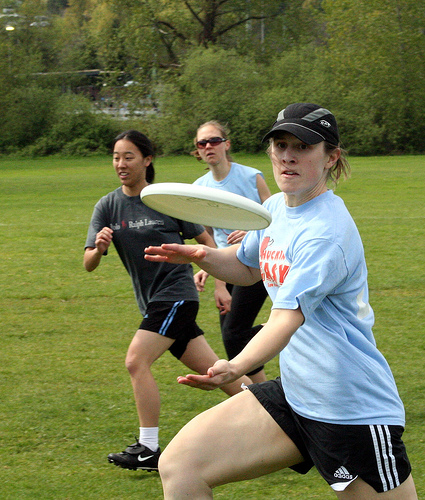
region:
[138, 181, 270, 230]
flying white frizbee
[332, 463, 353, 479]
logo on black pants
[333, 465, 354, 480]
white adidas symbol on shorts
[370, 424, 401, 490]
decorative stripes on pants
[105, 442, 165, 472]
nike athletic shoes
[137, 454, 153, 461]
nike logo on a black shoe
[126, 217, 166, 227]
Word spelling "Ralph Lauren"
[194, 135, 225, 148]
brown colored sunglasses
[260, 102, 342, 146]
black and grey hat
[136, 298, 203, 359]
pair of black and blue shorts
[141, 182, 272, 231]
Frisbee flying in the air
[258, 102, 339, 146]
Black hat on a woman's head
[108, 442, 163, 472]
A black, Nike brand shoe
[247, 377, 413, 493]
Black, ADIDAS brand shorts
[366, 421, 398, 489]
Three stripes on a pair of shorts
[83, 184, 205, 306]
Dark gray shirt on a woman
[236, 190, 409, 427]
Light blue shirt on a woman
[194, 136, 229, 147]
Sunglasses on a woman's face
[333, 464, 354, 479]
Logo on a pair of shorts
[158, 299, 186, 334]
Twin stripes on a pair of shorts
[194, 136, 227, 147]
woman wearing dark sunglasses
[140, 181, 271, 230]
white frisbee in air in front of women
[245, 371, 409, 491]
black shorts with three white stripes down side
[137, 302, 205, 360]
black shorts with two white stripes down side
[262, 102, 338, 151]
woman wearing black cap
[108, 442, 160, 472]
black cleats with white Nike logo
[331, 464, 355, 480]
Addidas logo on black shorts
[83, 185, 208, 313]
gray shirt with Ralph Lauren written on it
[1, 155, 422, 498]
green grass beneath women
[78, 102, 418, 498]
women playing frisbee on grass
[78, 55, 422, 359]
people playing freesbe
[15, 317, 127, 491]
a field of grass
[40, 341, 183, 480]
a field of short green grass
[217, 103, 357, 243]
a person wearing aht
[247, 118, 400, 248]
a person wearin ga black hat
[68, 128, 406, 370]
three people playing freesbee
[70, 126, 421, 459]
three people in an area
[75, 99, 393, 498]
people playing game of frisbee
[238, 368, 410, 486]
shorts on the person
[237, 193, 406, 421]
shirt on the person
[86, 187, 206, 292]
shirt on the person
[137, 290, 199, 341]
shorts on the person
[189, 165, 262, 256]
shirt on the person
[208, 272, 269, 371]
pants on the person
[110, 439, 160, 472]
shoe on the person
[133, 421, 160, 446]
sock on the person